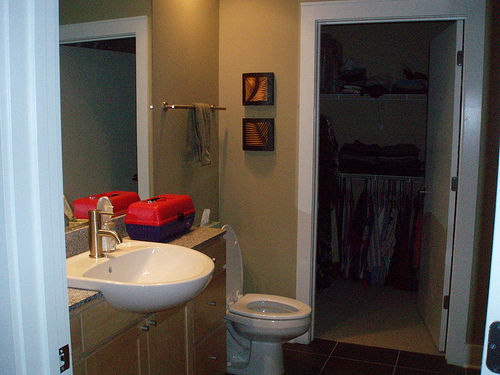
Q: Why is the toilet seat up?
A: Someone used the toilet.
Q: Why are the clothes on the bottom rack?
A: This is a child's closet.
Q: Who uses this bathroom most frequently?
A: A young child.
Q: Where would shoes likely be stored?
A: On the top shelf.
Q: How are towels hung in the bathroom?
A: On the towel rack.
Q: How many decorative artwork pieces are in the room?
A: Two artwork pieces are in the room.